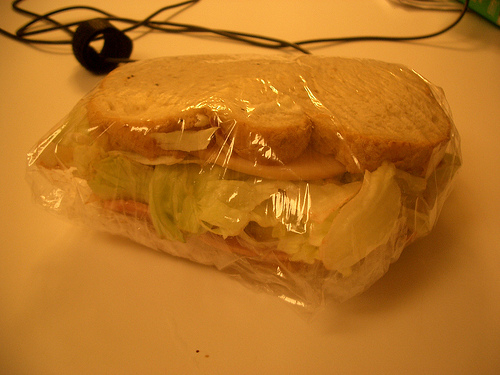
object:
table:
[0, 0, 500, 374]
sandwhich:
[32, 52, 463, 305]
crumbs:
[180, 347, 213, 359]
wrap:
[21, 50, 466, 317]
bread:
[86, 52, 454, 163]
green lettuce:
[45, 143, 463, 278]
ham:
[192, 145, 346, 181]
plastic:
[21, 51, 465, 315]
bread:
[88, 198, 420, 276]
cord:
[0, 0, 469, 64]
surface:
[2, 1, 498, 372]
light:
[268, 190, 313, 235]